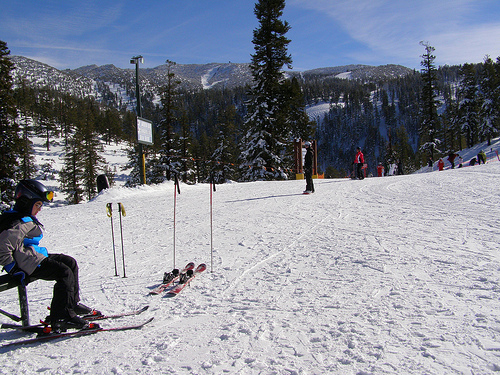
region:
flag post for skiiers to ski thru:
[146, 164, 232, 297]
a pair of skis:
[136, 260, 216, 300]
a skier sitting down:
[4, 166, 146, 337]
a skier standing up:
[295, 132, 321, 198]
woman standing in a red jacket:
[348, 137, 373, 183]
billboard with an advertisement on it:
[130, 105, 165, 152]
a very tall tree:
[244, 3, 311, 184]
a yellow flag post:
[111, 197, 130, 219]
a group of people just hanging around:
[428, 143, 490, 179]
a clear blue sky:
[33, 5, 229, 60]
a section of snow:
[211, 259, 308, 313]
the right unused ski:
[156, 252, 217, 306]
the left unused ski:
[141, 247, 197, 292]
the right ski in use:
[16, 321, 175, 347]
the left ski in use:
[17, 280, 153, 326]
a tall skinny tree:
[48, 107, 93, 214]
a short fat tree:
[394, 127, 431, 181]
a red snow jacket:
[352, 138, 371, 173]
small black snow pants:
[300, 164, 327, 198]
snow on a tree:
[245, 101, 275, 174]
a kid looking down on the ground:
[1, 175, 96, 336]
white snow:
[250, 227, 480, 352]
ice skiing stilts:
[104, 200, 135, 284]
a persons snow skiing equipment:
[145, 167, 220, 305]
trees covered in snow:
[37, 67, 132, 175]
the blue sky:
[12, 0, 216, 65]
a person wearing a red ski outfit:
[347, 144, 372, 179]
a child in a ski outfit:
[7, 170, 105, 345]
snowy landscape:
[97, 60, 457, 180]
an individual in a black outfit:
[298, 135, 322, 197]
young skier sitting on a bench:
[0, 176, 103, 338]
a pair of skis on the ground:
[148, 259, 205, 297]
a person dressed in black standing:
[300, 139, 316, 197]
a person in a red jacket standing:
[351, 144, 366, 180]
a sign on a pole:
[133, 113, 154, 183]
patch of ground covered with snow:
[244, 211, 419, 326]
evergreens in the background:
[179, 89, 291, 181]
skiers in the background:
[435, 144, 491, 173]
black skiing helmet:
[12, 176, 54, 205]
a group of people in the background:
[372, 153, 404, 178]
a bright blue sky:
[34, 2, 231, 50]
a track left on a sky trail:
[229, 220, 301, 285]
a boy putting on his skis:
[3, 177, 166, 353]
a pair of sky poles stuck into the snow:
[99, 195, 134, 290]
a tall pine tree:
[241, 3, 301, 178]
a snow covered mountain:
[314, 63, 496, 147]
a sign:
[131, 114, 155, 148]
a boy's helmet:
[19, 176, 55, 205]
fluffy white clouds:
[334, 10, 494, 53]